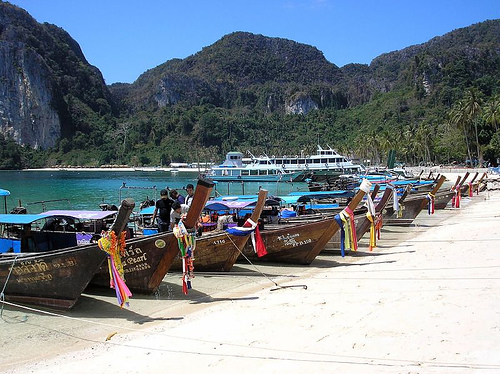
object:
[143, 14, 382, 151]
mountains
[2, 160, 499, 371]
sand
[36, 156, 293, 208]
water